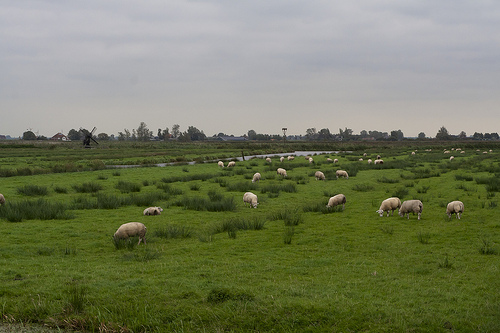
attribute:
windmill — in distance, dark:
[72, 122, 109, 154]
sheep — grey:
[395, 194, 425, 222]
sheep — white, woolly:
[238, 185, 260, 213]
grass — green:
[11, 132, 490, 330]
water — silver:
[152, 147, 347, 165]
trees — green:
[57, 104, 330, 144]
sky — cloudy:
[26, 14, 473, 111]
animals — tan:
[316, 183, 493, 245]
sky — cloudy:
[30, 3, 497, 133]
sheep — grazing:
[89, 194, 167, 251]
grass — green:
[189, 226, 470, 326]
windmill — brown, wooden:
[41, 117, 114, 160]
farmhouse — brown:
[29, 112, 129, 157]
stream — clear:
[103, 134, 359, 195]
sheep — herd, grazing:
[157, 158, 495, 287]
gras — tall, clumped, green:
[86, 167, 336, 262]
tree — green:
[269, 99, 489, 166]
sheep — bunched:
[93, 167, 492, 257]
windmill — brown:
[49, 118, 121, 145]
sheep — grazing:
[98, 148, 456, 294]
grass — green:
[16, 134, 473, 316]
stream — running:
[125, 144, 353, 165]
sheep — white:
[98, 175, 457, 243]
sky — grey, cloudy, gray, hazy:
[10, 6, 491, 138]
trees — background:
[52, 117, 372, 171]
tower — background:
[263, 114, 328, 153]